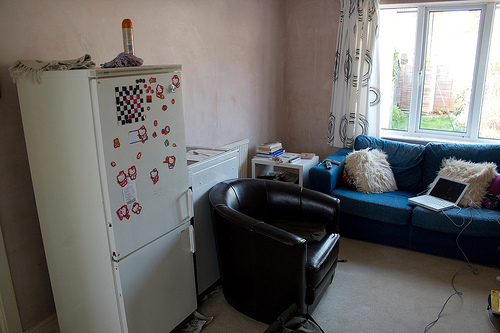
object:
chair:
[205, 175, 347, 327]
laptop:
[407, 174, 471, 212]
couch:
[307, 133, 500, 272]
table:
[251, 152, 320, 188]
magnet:
[114, 203, 132, 222]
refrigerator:
[14, 64, 201, 333]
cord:
[423, 195, 482, 332]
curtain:
[324, 0, 382, 151]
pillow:
[428, 154, 500, 211]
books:
[258, 139, 284, 150]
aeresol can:
[121, 18, 136, 55]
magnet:
[130, 200, 145, 215]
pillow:
[343, 146, 400, 195]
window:
[380, 0, 500, 145]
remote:
[317, 158, 341, 166]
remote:
[325, 160, 332, 170]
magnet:
[114, 169, 129, 189]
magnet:
[126, 163, 138, 182]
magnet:
[148, 166, 161, 186]